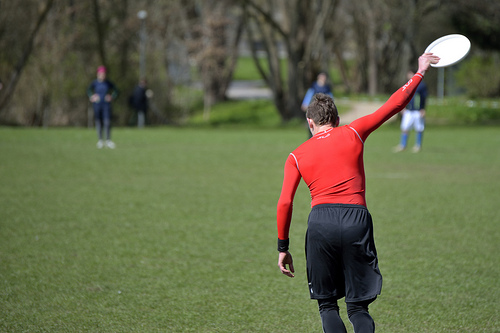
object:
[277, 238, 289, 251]
wrist band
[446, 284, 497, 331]
grass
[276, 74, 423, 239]
shirt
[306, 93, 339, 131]
hair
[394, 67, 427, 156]
people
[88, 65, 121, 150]
people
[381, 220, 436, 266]
ground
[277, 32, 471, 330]
boy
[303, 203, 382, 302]
shorts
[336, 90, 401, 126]
pathway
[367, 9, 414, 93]
tree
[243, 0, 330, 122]
tree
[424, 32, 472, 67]
frisbee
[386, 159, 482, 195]
ground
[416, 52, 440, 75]
male's hand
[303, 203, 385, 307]
shorts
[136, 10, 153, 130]
light pole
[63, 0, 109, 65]
tree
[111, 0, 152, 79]
tree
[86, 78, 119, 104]
shirt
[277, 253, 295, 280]
hand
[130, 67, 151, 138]
people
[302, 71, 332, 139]
people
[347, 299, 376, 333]
socks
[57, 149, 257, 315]
field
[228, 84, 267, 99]
path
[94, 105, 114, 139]
jeans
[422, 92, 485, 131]
plants